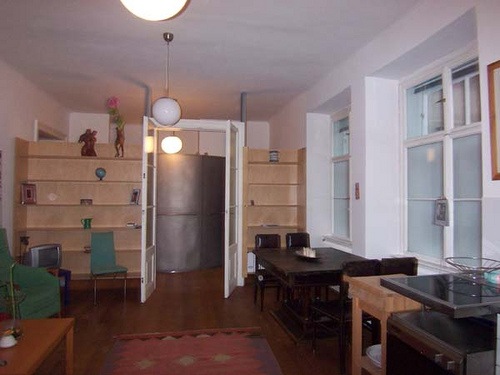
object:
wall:
[269, 0, 499, 285]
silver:
[147, 152, 225, 274]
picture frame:
[130, 189, 142, 205]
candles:
[303, 247, 316, 258]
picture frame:
[20, 183, 37, 204]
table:
[49, 269, 71, 307]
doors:
[139, 115, 246, 303]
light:
[151, 97, 181, 126]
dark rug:
[274, 300, 349, 341]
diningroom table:
[252, 247, 368, 334]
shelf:
[242, 146, 306, 278]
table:
[252, 232, 369, 334]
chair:
[253, 233, 282, 311]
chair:
[282, 232, 329, 302]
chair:
[343, 272, 430, 374]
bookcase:
[13, 140, 142, 281]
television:
[23, 244, 63, 270]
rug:
[96, 326, 280, 375]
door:
[396, 79, 490, 267]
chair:
[90, 231, 128, 306]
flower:
[107, 95, 121, 108]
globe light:
[160, 136, 183, 154]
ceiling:
[152, 58, 272, 88]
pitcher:
[80, 218, 93, 230]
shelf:
[13, 137, 142, 282]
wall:
[0, 58, 68, 236]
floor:
[31, 265, 377, 375]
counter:
[379, 272, 499, 319]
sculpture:
[78, 129, 98, 157]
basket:
[445, 256, 500, 280]